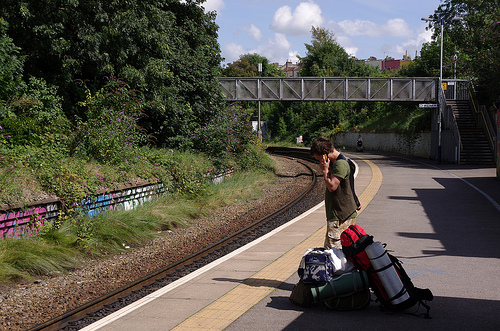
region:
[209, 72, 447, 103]
gray walkway over the tracks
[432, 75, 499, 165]
stairs leading to the walkway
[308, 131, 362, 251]
man talking on the phone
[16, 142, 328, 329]
railroad tracks under the walkway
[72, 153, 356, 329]
white curb along the tracks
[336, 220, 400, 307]
red luggage next to the man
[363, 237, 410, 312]
white luggage next to the man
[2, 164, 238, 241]
graffiti on the wall along the tracks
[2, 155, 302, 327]
rocks near the track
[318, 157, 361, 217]
man wearing a green shirt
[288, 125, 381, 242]
man is talking by cell phone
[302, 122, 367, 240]
man wears green shirt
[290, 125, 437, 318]
luggage next a man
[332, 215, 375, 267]
red backpack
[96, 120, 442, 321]
man stands in front a railroad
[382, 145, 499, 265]
shadow cast on platform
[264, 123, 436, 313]
man stand on train station platform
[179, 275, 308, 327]
a yellow line on train platform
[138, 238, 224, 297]
a white line on border of train platform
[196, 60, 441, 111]
a bridge on top of railroad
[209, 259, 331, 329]
The shadows are on the pavement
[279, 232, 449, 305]
The man has luggage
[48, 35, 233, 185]
The leaves are green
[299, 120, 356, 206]
The person is on the phone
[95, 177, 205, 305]
The tracks are metal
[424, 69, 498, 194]
The stairs are metal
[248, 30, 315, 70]
The sky is blue with clouds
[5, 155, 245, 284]
The grass is green and long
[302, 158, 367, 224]
The person has a green shirt on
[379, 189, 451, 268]
The pavement is light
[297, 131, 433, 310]
man and luggage on platform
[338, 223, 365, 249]
top of red suitcase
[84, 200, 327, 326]
white line of edge of platform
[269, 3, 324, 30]
white cloud in sky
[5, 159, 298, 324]
gravel on side of track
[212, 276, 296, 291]
shadow of man on platform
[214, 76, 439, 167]
walkway over train tracks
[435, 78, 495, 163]
stairwell leading to walkway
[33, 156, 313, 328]
metal rail of train track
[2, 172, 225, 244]
multi colored short wall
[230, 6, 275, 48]
white clouds in blue sky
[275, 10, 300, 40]
white clouds in blue sky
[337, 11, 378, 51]
white clouds in blue sky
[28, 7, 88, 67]
green leaves on trees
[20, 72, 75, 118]
green leaves on trees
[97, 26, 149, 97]
green leaves on trees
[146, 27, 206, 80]
green leaves on trees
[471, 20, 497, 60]
green leaves on trees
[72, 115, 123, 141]
green leaves on trees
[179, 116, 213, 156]
green leaves on trees